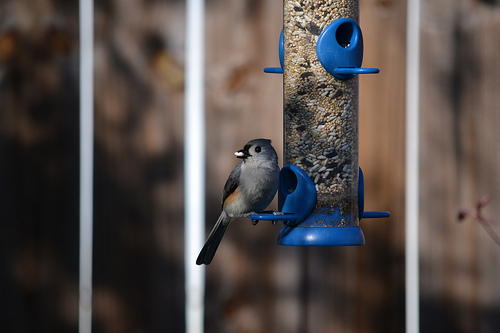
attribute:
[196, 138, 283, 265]
bird — gry, perched, gray, orange, red, little, black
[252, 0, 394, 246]
feeder — blue, cylinder, transparent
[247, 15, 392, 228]
trays — blue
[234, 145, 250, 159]
beak — white, black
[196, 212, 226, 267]
tail — gray, dark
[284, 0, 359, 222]
seed — black, white, tan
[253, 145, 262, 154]
eye — black, round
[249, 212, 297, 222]
perch — blue, plastic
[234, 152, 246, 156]
seed — white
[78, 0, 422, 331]
fence — white, metal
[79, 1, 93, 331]
pole — white, tall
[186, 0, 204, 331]
pole — white, tall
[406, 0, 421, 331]
pole — white, tall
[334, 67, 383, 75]
perch — blue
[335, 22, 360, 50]
hole — blue